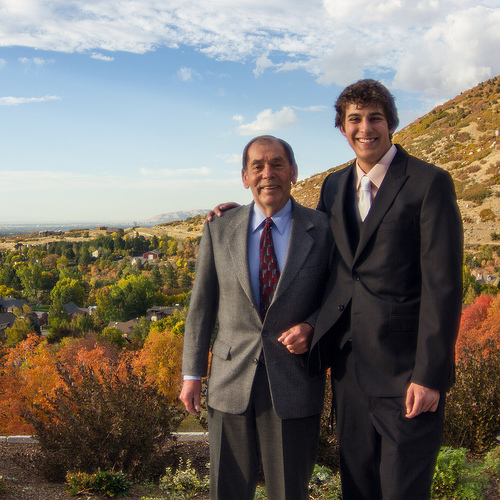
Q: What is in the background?
A: Hillside.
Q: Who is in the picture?
A: Men.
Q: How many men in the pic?
A: 2.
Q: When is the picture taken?
A: Autumn.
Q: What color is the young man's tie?
A: White.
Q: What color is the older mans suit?
A: Gray.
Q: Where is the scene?
A: A mountainside.